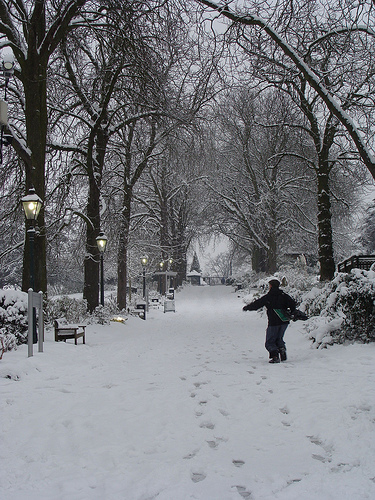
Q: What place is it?
A: It is a park.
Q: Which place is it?
A: It is a park.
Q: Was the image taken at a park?
A: Yes, it was taken in a park.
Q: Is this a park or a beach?
A: It is a park.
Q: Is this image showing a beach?
A: No, the picture is showing a park.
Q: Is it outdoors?
A: Yes, it is outdoors.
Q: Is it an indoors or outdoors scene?
A: It is outdoors.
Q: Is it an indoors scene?
A: No, it is outdoors.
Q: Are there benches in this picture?
A: Yes, there is a bench.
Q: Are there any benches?
A: Yes, there is a bench.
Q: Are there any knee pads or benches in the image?
A: Yes, there is a bench.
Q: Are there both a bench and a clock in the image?
A: No, there is a bench but no clocks.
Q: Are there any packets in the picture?
A: No, there are no packets.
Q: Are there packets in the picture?
A: No, there are no packets.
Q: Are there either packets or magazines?
A: No, there are no packets or magazines.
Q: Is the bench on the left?
A: Yes, the bench is on the left of the image.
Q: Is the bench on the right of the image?
A: No, the bench is on the left of the image.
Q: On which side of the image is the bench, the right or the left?
A: The bench is on the left of the image.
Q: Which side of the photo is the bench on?
A: The bench is on the left of the image.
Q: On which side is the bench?
A: The bench is on the left of the image.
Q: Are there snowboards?
A: Yes, there is a snowboard.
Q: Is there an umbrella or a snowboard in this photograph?
A: Yes, there is a snowboard.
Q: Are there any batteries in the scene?
A: No, there are no batteries.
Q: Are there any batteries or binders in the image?
A: No, there are no batteries or binders.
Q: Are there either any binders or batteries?
A: No, there are no batteries or binders.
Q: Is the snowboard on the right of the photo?
A: Yes, the snowboard is on the right of the image.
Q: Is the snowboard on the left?
A: No, the snowboard is on the right of the image.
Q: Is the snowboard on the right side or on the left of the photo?
A: The snowboard is on the right of the image.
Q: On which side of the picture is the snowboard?
A: The snowboard is on the right of the image.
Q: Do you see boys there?
A: No, there are no boys.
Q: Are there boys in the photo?
A: No, there are no boys.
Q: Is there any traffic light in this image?
A: No, there are no traffic lights.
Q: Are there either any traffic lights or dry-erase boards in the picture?
A: No, there are no traffic lights or dry-erase boards.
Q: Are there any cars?
A: No, there are no cars.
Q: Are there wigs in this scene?
A: No, there are no wigs.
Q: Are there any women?
A: No, there are no women.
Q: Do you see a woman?
A: No, there are no women.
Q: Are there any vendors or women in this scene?
A: No, there are no women or vendors.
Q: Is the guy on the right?
A: Yes, the guy is on the right of the image.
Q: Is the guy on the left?
A: No, the guy is on the right of the image.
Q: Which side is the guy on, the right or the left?
A: The guy is on the right of the image.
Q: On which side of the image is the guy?
A: The guy is on the right of the image.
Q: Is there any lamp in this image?
A: Yes, there is a lamp.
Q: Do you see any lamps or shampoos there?
A: Yes, there is a lamp.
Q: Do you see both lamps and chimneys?
A: No, there is a lamp but no chimneys.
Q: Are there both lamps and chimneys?
A: No, there is a lamp but no chimneys.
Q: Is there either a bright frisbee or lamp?
A: Yes, there is a bright lamp.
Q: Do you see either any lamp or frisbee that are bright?
A: Yes, the lamp is bright.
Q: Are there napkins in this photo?
A: No, there are no napkins.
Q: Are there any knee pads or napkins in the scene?
A: No, there are no napkins or knee pads.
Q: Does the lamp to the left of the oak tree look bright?
A: Yes, the lamp is bright.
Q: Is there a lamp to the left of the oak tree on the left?
A: Yes, there is a lamp to the left of the oak tree.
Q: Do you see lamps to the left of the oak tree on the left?
A: Yes, there is a lamp to the left of the oak tree.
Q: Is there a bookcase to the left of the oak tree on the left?
A: No, there is a lamp to the left of the oak.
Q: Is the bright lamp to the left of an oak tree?
A: Yes, the lamp is to the left of an oak tree.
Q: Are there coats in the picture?
A: Yes, there is a coat.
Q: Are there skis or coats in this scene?
A: Yes, there is a coat.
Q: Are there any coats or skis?
A: Yes, there is a coat.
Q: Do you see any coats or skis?
A: Yes, there is a coat.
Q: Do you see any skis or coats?
A: Yes, there is a coat.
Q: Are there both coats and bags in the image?
A: No, there is a coat but no bags.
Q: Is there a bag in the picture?
A: No, there are no bags.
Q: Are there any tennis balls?
A: No, there are no tennis balls.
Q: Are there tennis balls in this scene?
A: No, there are no tennis balls.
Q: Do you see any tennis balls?
A: No, there are no tennis balls.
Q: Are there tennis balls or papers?
A: No, there are no tennis balls or papers.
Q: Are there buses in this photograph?
A: No, there are no buses.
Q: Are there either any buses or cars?
A: No, there are no buses or cars.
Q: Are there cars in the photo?
A: No, there are no cars.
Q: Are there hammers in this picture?
A: No, there are no hammers.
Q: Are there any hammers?
A: No, there are no hammers.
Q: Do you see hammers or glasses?
A: No, there are no hammers or glasses.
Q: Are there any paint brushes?
A: No, there are no paint brushes.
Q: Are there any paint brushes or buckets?
A: No, there are no paint brushes or buckets.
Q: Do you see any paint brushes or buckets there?
A: No, there are no paint brushes or buckets.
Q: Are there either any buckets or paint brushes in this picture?
A: No, there are no paint brushes or buckets.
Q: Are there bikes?
A: No, there are no bikes.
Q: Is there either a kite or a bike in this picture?
A: No, there are no bikes or kites.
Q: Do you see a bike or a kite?
A: No, there are no bikes or kites.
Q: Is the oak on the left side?
A: Yes, the oak is on the left of the image.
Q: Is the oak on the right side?
A: No, the oak is on the left of the image.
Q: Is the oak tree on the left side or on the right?
A: The oak tree is on the left of the image.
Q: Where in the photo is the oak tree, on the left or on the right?
A: The oak tree is on the left of the image.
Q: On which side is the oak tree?
A: The oak tree is on the left of the image.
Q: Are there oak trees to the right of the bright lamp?
A: Yes, there is an oak tree to the right of the lamp.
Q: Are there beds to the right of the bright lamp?
A: No, there is an oak tree to the right of the lamp.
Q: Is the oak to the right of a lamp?
A: Yes, the oak is to the right of a lamp.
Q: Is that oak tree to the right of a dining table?
A: No, the oak tree is to the right of a lamp.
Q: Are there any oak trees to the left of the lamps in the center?
A: Yes, there is an oak tree to the left of the lamps.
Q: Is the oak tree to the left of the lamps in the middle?
A: Yes, the oak tree is to the left of the lamps.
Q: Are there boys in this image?
A: No, there are no boys.